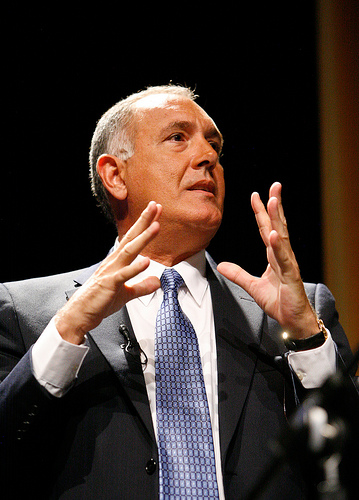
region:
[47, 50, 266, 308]
the head of a man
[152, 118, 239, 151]
the eyes of a man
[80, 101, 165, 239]
the ear of a man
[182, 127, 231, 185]
the nose of a man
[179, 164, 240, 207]
the mouth of a man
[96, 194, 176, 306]
the fingers of a man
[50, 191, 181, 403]
the hand of a man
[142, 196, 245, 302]
the chin of a man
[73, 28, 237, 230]
the hair of a man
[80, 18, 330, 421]
a man wearing a suit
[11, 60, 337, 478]
man in a suit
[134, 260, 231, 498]
tie on the man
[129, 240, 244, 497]
white shirt on man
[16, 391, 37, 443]
button on man's arm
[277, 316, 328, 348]
watch on the man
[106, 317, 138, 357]
mic on the man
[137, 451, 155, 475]
button on the suit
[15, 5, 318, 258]
dark backdrop in image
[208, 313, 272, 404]
shadow from man's hands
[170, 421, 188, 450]
pattern on the tie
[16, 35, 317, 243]
Screen is black color.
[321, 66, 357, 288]
Wall is brown color.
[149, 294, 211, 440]
Tie is blue and black color.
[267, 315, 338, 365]
Man is wearing watch in left hand.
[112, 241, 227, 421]
Man is wearing white inner shirt.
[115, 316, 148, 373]
Mike is clipped in coat.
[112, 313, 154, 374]
Mike is black color.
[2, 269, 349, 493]
Man is wearing black coat.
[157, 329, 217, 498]
Tie is checked design.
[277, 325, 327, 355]
Watch strap is black color.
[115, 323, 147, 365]
a microphone on the lapel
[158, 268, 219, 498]
a tie with no dimple in the knot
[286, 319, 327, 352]
a watch on a man's wrist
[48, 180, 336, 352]
hands being used in a gesture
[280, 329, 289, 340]
a reflection of light on the watch band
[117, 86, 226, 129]
receding hairline of a man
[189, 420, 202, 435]
squares on a necktie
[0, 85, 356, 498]
man in a gray suit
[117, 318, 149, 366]
microphone with a loop of wire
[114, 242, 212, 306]
collar of a white shirt